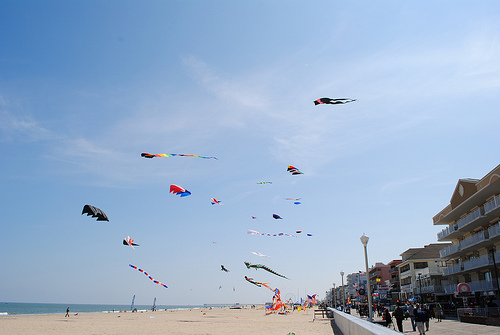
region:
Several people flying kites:
[80, 96, 432, 334]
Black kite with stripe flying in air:
[311, 96, 358, 106]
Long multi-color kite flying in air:
[135, 150, 220, 158]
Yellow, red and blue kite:
[167, 184, 192, 199]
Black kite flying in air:
[80, 203, 111, 223]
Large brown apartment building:
[431, 166, 498, 308]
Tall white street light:
[359, 231, 375, 321]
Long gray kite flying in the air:
[242, 259, 290, 280]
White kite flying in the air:
[248, 249, 268, 261]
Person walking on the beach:
[62, 304, 72, 317]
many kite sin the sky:
[70, 67, 366, 296]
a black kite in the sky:
[74, 195, 119, 228]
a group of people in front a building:
[350, 280, 467, 330]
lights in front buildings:
[326, 230, 376, 315]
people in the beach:
[50, 295, 210, 320]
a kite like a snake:
[122, 260, 177, 287]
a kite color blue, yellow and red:
[162, 175, 192, 200]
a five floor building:
[428, 167, 498, 314]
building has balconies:
[429, 165, 498, 318]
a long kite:
[239, 255, 294, 284]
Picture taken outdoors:
[11, 5, 496, 334]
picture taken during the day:
[47, 69, 479, 334]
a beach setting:
[106, 314, 286, 322]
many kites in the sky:
[36, 93, 385, 323]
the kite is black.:
[81, 202, 111, 223]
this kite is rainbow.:
[142, 151, 216, 161]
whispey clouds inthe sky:
[60, 47, 281, 89]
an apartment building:
[437, 203, 499, 274]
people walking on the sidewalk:
[391, 296, 426, 329]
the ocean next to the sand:
[19, 301, 53, 309]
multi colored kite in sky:
[116, 123, 221, 178]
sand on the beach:
[105, 302, 253, 332]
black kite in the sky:
[66, 183, 126, 244]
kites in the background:
[220, 249, 282, 312]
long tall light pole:
[334, 220, 386, 317]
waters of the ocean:
[4, 290, 65, 318]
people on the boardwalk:
[367, 288, 424, 333]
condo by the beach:
[404, 180, 499, 317]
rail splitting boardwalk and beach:
[329, 301, 376, 332]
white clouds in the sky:
[179, 87, 284, 142]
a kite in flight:
[311, 94, 355, 106]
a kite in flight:
[284, 162, 301, 178]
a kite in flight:
[139, 149, 217, 161]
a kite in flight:
[166, 180, 190, 197]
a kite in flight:
[79, 202, 109, 223]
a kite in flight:
[119, 233, 140, 249]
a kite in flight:
[126, 261, 168, 291]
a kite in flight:
[219, 262, 231, 274]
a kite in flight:
[241, 274, 271, 291]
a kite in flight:
[243, 260, 285, 279]